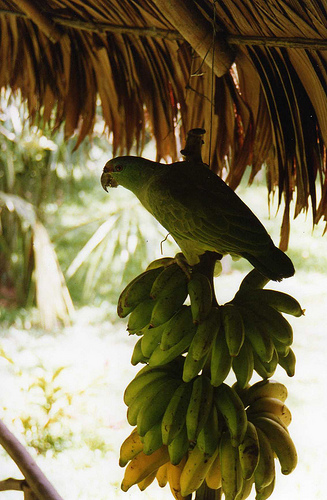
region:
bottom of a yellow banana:
[119, 467, 140, 493]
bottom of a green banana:
[179, 361, 201, 381]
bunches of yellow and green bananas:
[108, 379, 302, 498]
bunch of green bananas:
[123, 357, 243, 433]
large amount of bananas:
[119, 267, 307, 499]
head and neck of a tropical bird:
[95, 154, 150, 213]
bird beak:
[98, 174, 118, 193]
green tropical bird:
[99, 154, 305, 283]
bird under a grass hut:
[0, 0, 326, 266]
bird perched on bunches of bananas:
[96, 151, 313, 499]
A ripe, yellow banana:
[256, 414, 302, 476]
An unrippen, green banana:
[214, 379, 249, 449]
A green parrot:
[100, 153, 297, 284]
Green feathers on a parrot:
[165, 198, 212, 232]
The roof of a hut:
[3, 0, 325, 152]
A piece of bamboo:
[164, 0, 242, 77]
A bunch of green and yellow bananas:
[116, 266, 301, 496]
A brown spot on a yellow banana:
[278, 403, 286, 416]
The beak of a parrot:
[96, 171, 121, 194]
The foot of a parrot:
[159, 246, 195, 282]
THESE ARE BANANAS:
[111, 248, 310, 498]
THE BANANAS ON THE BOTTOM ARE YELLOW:
[120, 381, 308, 499]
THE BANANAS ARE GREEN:
[110, 252, 299, 463]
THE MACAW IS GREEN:
[96, 143, 296, 287]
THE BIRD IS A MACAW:
[97, 151, 305, 296]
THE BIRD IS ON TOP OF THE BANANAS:
[91, 148, 305, 293]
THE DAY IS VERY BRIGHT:
[2, 88, 325, 493]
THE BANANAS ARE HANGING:
[106, 251, 306, 499]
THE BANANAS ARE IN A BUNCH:
[100, 253, 324, 499]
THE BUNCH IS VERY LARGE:
[107, 248, 322, 498]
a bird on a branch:
[74, 109, 296, 323]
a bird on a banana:
[85, 113, 300, 320]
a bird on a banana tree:
[72, 122, 323, 356]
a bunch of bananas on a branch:
[129, 220, 289, 499]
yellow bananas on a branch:
[99, 230, 316, 480]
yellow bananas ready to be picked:
[79, 218, 320, 484]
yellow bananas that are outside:
[103, 230, 311, 497]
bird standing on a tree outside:
[65, 125, 310, 304]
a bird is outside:
[51, 101, 291, 355]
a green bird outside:
[71, 109, 326, 336]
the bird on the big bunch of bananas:
[94, 151, 291, 279]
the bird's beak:
[96, 168, 114, 191]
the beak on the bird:
[98, 171, 114, 189]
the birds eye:
[112, 159, 118, 168]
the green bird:
[97, 150, 292, 275]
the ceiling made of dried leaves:
[0, 0, 325, 192]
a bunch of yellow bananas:
[119, 432, 218, 498]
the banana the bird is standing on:
[149, 263, 189, 300]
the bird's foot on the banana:
[167, 248, 192, 279]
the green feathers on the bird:
[150, 163, 294, 276]